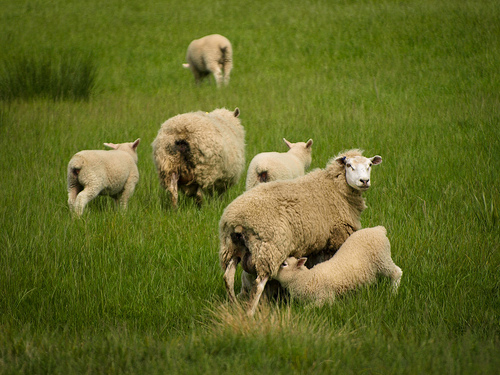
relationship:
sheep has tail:
[178, 30, 237, 87] [215, 39, 229, 57]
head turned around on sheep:
[339, 144, 376, 199] [209, 155, 386, 302]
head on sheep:
[331, 146, 382, 192] [207, 136, 382, 302]